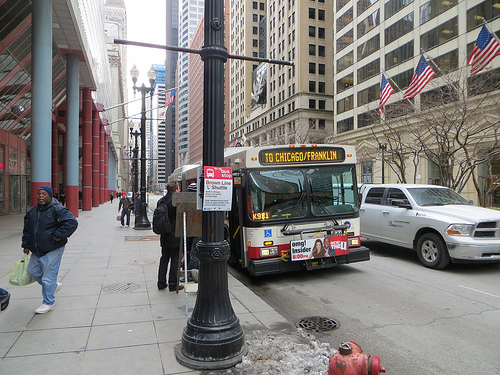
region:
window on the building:
[317, 65, 324, 75]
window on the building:
[307, 82, 315, 94]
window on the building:
[318, 47, 325, 60]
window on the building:
[306, 99, 314, 111]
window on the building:
[302, 41, 316, 55]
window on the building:
[307, 27, 317, 37]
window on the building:
[307, 9, 319, 20]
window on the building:
[312, 57, 334, 81]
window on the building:
[306, 7, 316, 25]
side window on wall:
[335, 112, 358, 137]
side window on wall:
[358, 107, 386, 132]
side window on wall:
[385, 102, 414, 115]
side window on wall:
[420, 86, 458, 103]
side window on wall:
[331, 98, 355, 114]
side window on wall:
[358, 88, 393, 122]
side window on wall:
[316, 97, 332, 114]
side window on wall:
[293, 117, 332, 129]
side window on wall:
[281, 122, 307, 134]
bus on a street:
[246, 140, 364, 280]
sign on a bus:
[256, 143, 343, 168]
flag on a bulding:
[465, 15, 497, 80]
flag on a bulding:
[401, 60, 461, 105]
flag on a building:
[365, 55, 397, 115]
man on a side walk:
[16, 178, 72, 319]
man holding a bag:
[18, 182, 78, 329]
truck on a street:
[380, 180, 492, 268]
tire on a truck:
[406, 228, 446, 261]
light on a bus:
[247, 242, 282, 262]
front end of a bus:
[242, 142, 360, 263]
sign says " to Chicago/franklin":
[261, 149, 340, 163]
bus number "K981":
[252, 209, 271, 220]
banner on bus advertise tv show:
[289, 238, 349, 259]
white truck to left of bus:
[356, 178, 498, 263]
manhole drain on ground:
[298, 316, 336, 333]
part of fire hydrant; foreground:
[324, 341, 386, 373]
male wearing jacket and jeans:
[23, 189, 73, 312]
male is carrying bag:
[10, 253, 33, 283]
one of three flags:
[404, 55, 435, 95]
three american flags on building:
[360, 23, 497, 121]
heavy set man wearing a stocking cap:
[6, 184, 78, 329]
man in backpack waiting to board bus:
[147, 175, 184, 292]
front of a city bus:
[233, 136, 368, 272]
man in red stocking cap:
[113, 190, 133, 226]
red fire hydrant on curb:
[321, 339, 386, 373]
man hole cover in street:
[297, 310, 342, 335]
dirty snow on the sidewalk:
[238, 320, 338, 372]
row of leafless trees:
[365, 100, 499, 198]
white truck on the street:
[362, 177, 499, 267]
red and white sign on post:
[192, 158, 234, 228]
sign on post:
[198, 159, 234, 221]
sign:
[200, 163, 243, 218]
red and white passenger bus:
[251, 135, 362, 268]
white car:
[374, 172, 499, 265]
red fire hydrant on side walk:
[320, 328, 380, 373]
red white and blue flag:
[368, 60, 396, 115]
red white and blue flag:
[400, 46, 447, 107]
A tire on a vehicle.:
[415, 234, 450, 269]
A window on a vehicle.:
[386, 187, 411, 210]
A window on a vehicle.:
[364, 187, 385, 204]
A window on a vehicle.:
[406, 186, 471, 206]